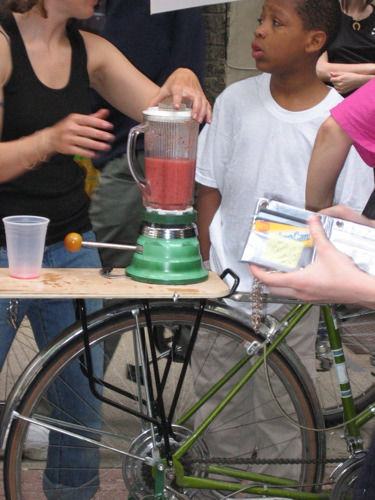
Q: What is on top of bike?
A: Blender.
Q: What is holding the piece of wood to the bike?
A: A black metal bracket.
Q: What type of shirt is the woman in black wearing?
A: A tank top.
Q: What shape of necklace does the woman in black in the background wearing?
A: A horseshoe.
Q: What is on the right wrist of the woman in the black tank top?
A: Bracelets.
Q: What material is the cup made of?
A: Plastic.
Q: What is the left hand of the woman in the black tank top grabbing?
A: The top of the blender.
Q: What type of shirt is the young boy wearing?
A: A white t-shirt.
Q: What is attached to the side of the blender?
A: A long handle.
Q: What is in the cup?
A: A small amount of red liquid.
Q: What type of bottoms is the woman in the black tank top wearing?
A: Blue jeans.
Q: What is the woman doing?
A: Making a smoothie.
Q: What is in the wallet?
A: Credit cards.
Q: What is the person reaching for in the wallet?
A: Money.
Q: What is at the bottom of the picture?
A: Bike.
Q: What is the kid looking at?
A: The woman.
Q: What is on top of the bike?
A: Blender.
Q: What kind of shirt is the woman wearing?
A: Tank top.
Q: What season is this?
A: Summer.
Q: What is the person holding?
A: Wallet.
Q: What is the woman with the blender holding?
A: The cover of the blender.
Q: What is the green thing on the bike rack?
A: A blender.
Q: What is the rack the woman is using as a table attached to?
A: A bicycle.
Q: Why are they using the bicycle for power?
A: To save energy.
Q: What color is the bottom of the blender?
A: Green.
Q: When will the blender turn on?
A: When the bike is pedaled.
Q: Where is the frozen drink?
A: In the blender.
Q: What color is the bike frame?
A: Green.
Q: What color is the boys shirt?
A: White.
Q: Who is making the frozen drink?
A: The woman.